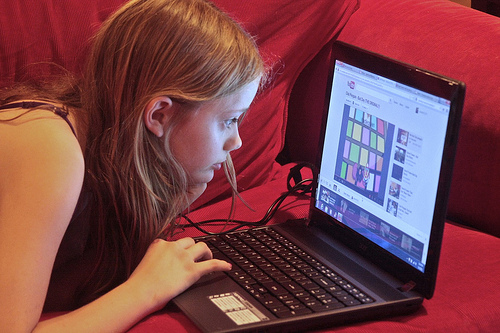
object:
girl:
[1, 1, 263, 332]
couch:
[1, 0, 500, 331]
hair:
[0, 0, 273, 314]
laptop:
[171, 40, 465, 332]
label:
[205, 290, 272, 325]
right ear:
[142, 95, 171, 137]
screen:
[312, 59, 453, 274]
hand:
[130, 235, 233, 302]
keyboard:
[189, 226, 377, 319]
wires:
[173, 178, 315, 234]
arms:
[0, 140, 134, 332]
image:
[332, 103, 395, 206]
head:
[89, 0, 266, 183]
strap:
[1, 101, 79, 137]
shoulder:
[1, 108, 87, 187]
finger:
[197, 258, 233, 276]